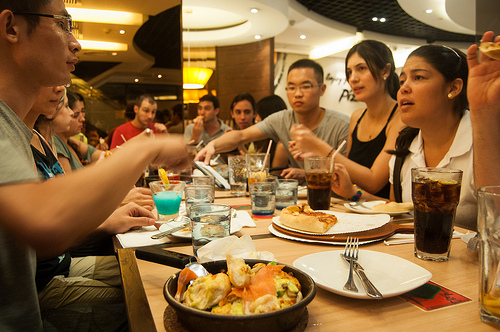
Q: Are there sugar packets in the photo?
A: No, there are no sugar packets.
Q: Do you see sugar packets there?
A: No, there are no sugar packets.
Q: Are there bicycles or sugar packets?
A: No, there are no sugar packets or bicycles.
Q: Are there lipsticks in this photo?
A: No, there are no lipsticks.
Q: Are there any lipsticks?
A: No, there are no lipsticks.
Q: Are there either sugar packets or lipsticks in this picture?
A: No, there are no lipsticks or sugar packets.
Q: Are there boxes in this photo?
A: No, there are no boxes.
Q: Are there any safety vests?
A: No, there are no safety vests.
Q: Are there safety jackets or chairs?
A: No, there are no safety jackets or chairs.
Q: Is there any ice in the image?
A: Yes, there is ice.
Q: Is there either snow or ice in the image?
A: Yes, there is ice.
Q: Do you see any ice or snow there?
A: Yes, there is ice.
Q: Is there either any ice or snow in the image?
A: Yes, there is ice.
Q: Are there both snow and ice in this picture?
A: No, there is ice but no snow.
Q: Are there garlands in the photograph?
A: No, there are no garlands.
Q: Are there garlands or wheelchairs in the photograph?
A: No, there are no garlands or wheelchairs.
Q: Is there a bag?
A: No, there are no bags.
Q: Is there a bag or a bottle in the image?
A: No, there are no bags or bottles.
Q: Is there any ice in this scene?
A: Yes, there is ice.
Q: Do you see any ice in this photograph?
A: Yes, there is ice.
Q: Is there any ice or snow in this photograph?
A: Yes, there is ice.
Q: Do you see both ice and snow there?
A: No, there is ice but no snow.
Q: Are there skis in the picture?
A: No, there are no skis.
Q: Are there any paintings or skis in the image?
A: No, there are no skis or paintings.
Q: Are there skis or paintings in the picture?
A: No, there are no skis or paintings.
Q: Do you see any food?
A: Yes, there is food.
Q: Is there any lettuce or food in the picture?
A: Yes, there is food.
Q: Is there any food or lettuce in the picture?
A: Yes, there is food.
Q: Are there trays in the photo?
A: No, there are no trays.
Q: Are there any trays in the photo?
A: No, there are no trays.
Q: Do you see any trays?
A: No, there are no trays.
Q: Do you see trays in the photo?
A: No, there are no trays.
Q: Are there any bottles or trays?
A: No, there are no trays or bottles.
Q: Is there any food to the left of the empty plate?
A: Yes, there is food to the left of the plate.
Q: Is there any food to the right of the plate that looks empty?
A: No, the food is to the left of the plate.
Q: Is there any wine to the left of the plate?
A: No, there is food to the left of the plate.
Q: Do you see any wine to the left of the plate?
A: No, there is food to the left of the plate.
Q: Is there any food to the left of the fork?
A: Yes, there is food to the left of the fork.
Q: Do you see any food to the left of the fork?
A: Yes, there is food to the left of the fork.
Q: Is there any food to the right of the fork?
A: No, the food is to the left of the fork.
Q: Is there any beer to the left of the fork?
A: No, there is food to the left of the fork.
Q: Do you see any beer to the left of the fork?
A: No, there is food to the left of the fork.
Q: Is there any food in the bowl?
A: Yes, there is food in the bowl.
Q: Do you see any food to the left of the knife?
A: Yes, there is food to the left of the knife.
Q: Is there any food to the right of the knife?
A: No, the food is to the left of the knife.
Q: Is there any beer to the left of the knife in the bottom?
A: No, there is food to the left of the knife.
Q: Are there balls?
A: No, there are no balls.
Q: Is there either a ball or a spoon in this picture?
A: No, there are no balls or spoons.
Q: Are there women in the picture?
A: Yes, there is a woman.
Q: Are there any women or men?
A: Yes, there is a woman.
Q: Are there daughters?
A: No, there are no daughters.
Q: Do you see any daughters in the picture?
A: No, there are no daughters.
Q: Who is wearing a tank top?
A: The woman is wearing a tank top.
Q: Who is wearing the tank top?
A: The woman is wearing a tank top.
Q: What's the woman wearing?
A: The woman is wearing a tank top.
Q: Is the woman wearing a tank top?
A: Yes, the woman is wearing a tank top.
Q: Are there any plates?
A: Yes, there is a plate.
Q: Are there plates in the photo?
A: Yes, there is a plate.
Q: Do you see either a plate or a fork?
A: Yes, there is a plate.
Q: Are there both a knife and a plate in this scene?
A: Yes, there are both a plate and a knife.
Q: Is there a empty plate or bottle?
A: Yes, there is an empty plate.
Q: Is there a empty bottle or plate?
A: Yes, there is an empty plate.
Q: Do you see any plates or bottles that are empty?
A: Yes, the plate is empty.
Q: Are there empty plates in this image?
A: Yes, there is an empty plate.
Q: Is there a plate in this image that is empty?
A: Yes, there is a plate that is empty.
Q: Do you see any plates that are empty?
A: Yes, there is a plate that is empty.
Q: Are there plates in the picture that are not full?
A: Yes, there is a empty plate.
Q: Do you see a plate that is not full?
A: Yes, there is a empty plate.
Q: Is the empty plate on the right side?
A: Yes, the plate is on the right of the image.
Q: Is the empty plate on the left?
A: No, the plate is on the right of the image.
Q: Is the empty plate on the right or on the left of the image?
A: The plate is on the right of the image.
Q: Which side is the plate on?
A: The plate is on the right of the image.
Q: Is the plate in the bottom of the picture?
A: Yes, the plate is in the bottom of the image.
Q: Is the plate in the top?
A: No, the plate is in the bottom of the image.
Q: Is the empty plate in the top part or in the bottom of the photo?
A: The plate is in the bottom of the image.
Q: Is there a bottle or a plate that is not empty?
A: No, there is a plate but it is empty.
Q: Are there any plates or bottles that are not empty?
A: No, there is a plate but it is empty.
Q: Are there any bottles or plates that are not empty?
A: No, there is a plate but it is empty.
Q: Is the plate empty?
A: Yes, the plate is empty.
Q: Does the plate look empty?
A: Yes, the plate is empty.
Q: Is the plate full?
A: No, the plate is empty.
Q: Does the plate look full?
A: No, the plate is empty.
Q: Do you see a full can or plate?
A: No, there is a plate but it is empty.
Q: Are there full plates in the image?
A: No, there is a plate but it is empty.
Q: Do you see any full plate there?
A: No, there is a plate but it is empty.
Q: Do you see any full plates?
A: No, there is a plate but it is empty.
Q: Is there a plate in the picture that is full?
A: No, there is a plate but it is empty.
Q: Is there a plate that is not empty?
A: No, there is a plate but it is empty.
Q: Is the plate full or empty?
A: The plate is empty.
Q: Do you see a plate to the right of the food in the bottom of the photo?
A: Yes, there is a plate to the right of the food.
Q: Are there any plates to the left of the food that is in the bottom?
A: No, the plate is to the right of the food.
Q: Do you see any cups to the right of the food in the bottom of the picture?
A: No, there is a plate to the right of the food.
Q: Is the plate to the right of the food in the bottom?
A: Yes, the plate is to the right of the food.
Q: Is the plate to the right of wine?
A: No, the plate is to the right of the food.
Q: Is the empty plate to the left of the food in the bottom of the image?
A: No, the plate is to the right of the food.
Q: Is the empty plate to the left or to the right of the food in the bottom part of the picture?
A: The plate is to the right of the food.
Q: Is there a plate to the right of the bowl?
A: Yes, there is a plate to the right of the bowl.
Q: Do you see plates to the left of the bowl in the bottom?
A: No, the plate is to the right of the bowl.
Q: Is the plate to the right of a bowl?
A: Yes, the plate is to the right of a bowl.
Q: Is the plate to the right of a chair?
A: No, the plate is to the right of a bowl.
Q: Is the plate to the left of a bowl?
A: No, the plate is to the right of a bowl.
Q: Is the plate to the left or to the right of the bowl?
A: The plate is to the right of the bowl.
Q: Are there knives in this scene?
A: Yes, there is a knife.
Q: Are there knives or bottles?
A: Yes, there is a knife.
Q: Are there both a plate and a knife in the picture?
A: Yes, there are both a knife and a plate.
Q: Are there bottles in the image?
A: No, there are no bottles.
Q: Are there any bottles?
A: No, there are no bottles.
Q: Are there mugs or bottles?
A: No, there are no bottles or mugs.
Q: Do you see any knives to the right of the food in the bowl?
A: Yes, there is a knife to the right of the food.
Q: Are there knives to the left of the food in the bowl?
A: No, the knife is to the right of the food.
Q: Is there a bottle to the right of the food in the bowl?
A: No, there is a knife to the right of the food.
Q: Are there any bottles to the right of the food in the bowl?
A: No, there is a knife to the right of the food.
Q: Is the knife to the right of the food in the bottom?
A: Yes, the knife is to the right of the food.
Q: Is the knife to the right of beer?
A: No, the knife is to the right of the food.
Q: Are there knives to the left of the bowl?
A: No, the knife is to the right of the bowl.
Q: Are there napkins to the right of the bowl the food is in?
A: No, there is a knife to the right of the bowl.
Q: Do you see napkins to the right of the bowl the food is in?
A: No, there is a knife to the right of the bowl.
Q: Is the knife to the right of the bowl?
A: Yes, the knife is to the right of the bowl.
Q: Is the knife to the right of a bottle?
A: No, the knife is to the right of the bowl.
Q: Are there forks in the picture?
A: Yes, there is a fork.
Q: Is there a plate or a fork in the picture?
A: Yes, there is a fork.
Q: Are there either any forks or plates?
A: Yes, there is a fork.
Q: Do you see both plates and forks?
A: Yes, there are both a fork and a plate.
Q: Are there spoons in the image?
A: No, there are no spoons.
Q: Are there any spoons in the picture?
A: No, there are no spoons.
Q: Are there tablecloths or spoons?
A: No, there are no spoons or tablecloths.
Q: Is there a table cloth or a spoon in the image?
A: No, there are no spoons or tablecloths.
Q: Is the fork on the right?
A: Yes, the fork is on the right of the image.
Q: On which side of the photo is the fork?
A: The fork is on the right of the image.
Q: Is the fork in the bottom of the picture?
A: Yes, the fork is in the bottom of the image.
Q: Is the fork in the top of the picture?
A: No, the fork is in the bottom of the image.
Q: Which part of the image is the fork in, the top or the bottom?
A: The fork is in the bottom of the image.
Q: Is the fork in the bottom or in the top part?
A: The fork is in the bottom of the image.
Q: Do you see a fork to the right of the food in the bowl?
A: Yes, there is a fork to the right of the food.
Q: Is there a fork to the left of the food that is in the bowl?
A: No, the fork is to the right of the food.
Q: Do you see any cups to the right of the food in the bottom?
A: No, there is a fork to the right of the food.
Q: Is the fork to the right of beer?
A: No, the fork is to the right of the food.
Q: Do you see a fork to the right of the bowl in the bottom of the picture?
A: Yes, there is a fork to the right of the bowl.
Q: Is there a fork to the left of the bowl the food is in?
A: No, the fork is to the right of the bowl.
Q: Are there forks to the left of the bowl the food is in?
A: No, the fork is to the right of the bowl.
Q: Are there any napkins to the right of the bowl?
A: No, there is a fork to the right of the bowl.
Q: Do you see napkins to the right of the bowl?
A: No, there is a fork to the right of the bowl.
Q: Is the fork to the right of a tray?
A: No, the fork is to the right of the bowl.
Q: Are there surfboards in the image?
A: No, there are no surfboards.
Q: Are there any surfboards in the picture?
A: No, there are no surfboards.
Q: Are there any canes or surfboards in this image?
A: No, there are no surfboards or canes.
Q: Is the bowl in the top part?
A: No, the bowl is in the bottom of the image.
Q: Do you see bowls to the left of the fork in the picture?
A: Yes, there is a bowl to the left of the fork.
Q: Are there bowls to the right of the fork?
A: No, the bowl is to the left of the fork.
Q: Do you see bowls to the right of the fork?
A: No, the bowl is to the left of the fork.